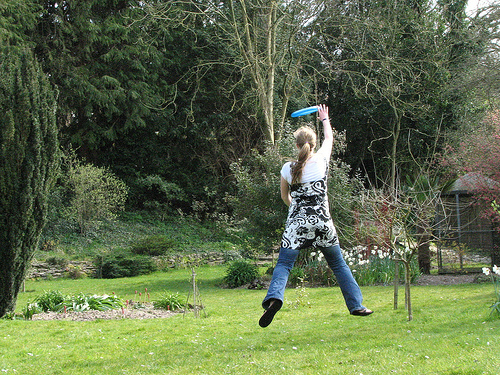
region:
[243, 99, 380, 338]
a person grabbing a frisbee.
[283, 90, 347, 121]
a person holding a blue frisbee.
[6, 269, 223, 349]
a patch of flowers.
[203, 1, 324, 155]
a tree in a garden.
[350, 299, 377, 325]
a right sandal on a person.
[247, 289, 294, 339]
a left foot on a person.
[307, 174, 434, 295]
white flowers in a field.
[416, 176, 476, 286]
a tree trunk.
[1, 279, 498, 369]
a patch of green grass.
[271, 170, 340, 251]
an artistic t-shirt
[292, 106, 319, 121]
blue Frisbee in the air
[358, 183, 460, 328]
tree barren of leaves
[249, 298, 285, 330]
sandal on woman's foot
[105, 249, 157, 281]
small green bush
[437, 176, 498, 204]
thatched roof on a gazebo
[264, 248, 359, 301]
denim jean pants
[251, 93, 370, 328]
woman jumping up catching a Frisbee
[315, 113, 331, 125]
wrist accessory on woman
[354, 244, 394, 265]
white flowers on stems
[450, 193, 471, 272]
brown support beam for gazebo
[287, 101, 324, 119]
blue frisbee in midair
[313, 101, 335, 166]
girls hand reaching for the frisbee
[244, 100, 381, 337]
girl catching frisbee in back yard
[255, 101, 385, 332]
both of her legs are in the air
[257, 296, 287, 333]
the sole of her shoe is brown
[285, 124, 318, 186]
she has her hair in a pony tail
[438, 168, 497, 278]
cage in the background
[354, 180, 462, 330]
newly planted trees with no leaves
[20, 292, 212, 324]
various plants in mulch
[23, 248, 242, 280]
rock wall against the hill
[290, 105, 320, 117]
Blue frisbee flying in the air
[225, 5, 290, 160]
Bare tree in background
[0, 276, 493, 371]
Grass female is playing on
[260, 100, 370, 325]
Female catching frisbee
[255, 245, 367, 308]
Blue jeans worn by female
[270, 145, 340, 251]
White shirt with design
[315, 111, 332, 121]
Wristwatch worn by female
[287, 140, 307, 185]
Ponytail worn by female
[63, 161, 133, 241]
Small trees in background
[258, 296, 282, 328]
Left shoe worn by female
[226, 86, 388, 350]
girl jumping off ground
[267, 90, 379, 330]
girl trying to catch frisbee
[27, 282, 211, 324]
garden with rocks and flowers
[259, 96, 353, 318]
girl has long ponytail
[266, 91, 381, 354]
girl wearing blue jeans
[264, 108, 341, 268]
girl wearing black and white top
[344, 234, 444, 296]
white flowers with green leaves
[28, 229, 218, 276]
rock ledge with bushes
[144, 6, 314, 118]
tree branches with no leaves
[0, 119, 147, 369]
green bush by garden